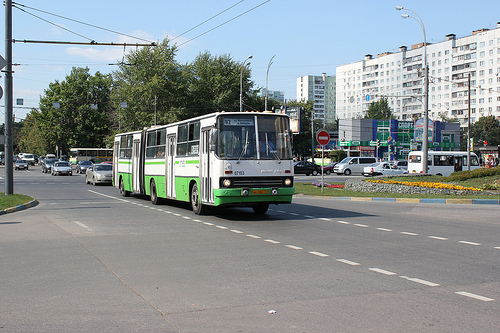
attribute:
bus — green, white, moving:
[84, 95, 310, 237]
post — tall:
[3, 1, 25, 193]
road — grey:
[6, 166, 499, 321]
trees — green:
[22, 46, 280, 167]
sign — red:
[316, 126, 333, 149]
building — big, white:
[294, 26, 499, 153]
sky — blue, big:
[2, 1, 490, 101]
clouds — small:
[61, 24, 186, 68]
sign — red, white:
[312, 123, 334, 193]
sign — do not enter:
[312, 122, 336, 197]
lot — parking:
[280, 135, 494, 195]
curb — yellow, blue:
[292, 180, 499, 216]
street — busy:
[6, 155, 498, 328]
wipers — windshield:
[224, 127, 296, 167]